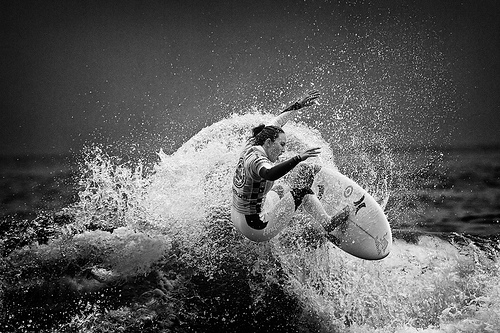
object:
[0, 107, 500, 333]
splash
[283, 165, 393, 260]
surf board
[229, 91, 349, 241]
man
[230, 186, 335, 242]
pants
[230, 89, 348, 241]
woman